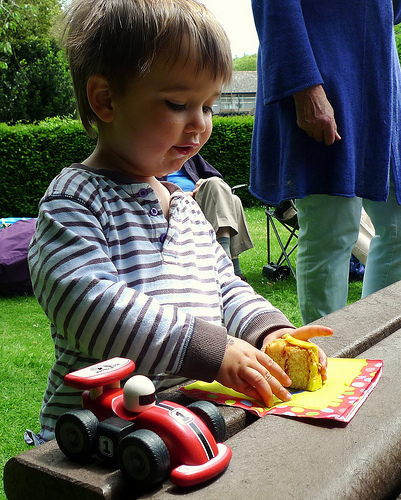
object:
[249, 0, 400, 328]
adult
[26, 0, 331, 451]
child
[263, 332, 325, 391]
cake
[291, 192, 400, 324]
blue jeans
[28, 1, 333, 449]
boy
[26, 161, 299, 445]
shirt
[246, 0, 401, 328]
woman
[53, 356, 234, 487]
car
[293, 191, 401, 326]
pants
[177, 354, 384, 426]
napkin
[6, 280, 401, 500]
table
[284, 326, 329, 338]
frosting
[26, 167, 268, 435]
stripes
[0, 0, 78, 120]
tree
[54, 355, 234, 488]
racecar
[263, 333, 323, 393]
food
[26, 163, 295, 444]
shirt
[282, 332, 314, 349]
frosting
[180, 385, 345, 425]
polka dots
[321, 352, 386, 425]
polka dots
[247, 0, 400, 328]
person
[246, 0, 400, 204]
shirt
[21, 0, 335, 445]
boy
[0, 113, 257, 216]
bush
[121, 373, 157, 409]
helmet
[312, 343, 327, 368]
frosting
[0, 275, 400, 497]
bench